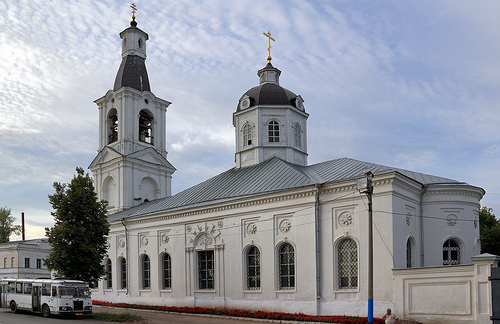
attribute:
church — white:
[108, 157, 420, 225]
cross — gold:
[265, 31, 273, 62]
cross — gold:
[129, 3, 136, 18]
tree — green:
[60, 189, 97, 272]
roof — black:
[257, 87, 291, 103]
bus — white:
[9, 279, 88, 314]